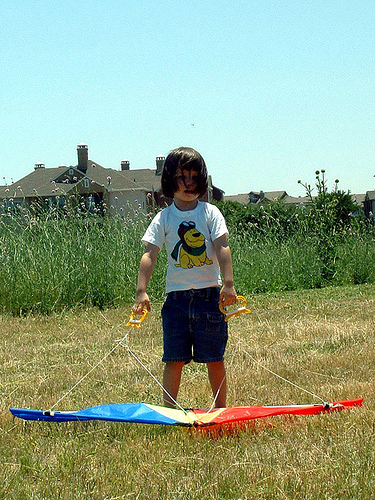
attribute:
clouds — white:
[223, 145, 282, 184]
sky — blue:
[1, 2, 363, 146]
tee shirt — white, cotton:
[140, 207, 232, 291]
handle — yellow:
[125, 306, 150, 332]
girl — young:
[137, 147, 239, 429]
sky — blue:
[2, 10, 331, 107]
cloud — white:
[229, 167, 285, 187]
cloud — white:
[251, 162, 296, 187]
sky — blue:
[204, 12, 339, 65]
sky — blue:
[2, 6, 98, 96]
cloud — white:
[95, 128, 129, 156]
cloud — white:
[256, 175, 294, 191]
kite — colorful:
[11, 396, 366, 425]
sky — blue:
[305, 6, 355, 67]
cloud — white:
[344, 167, 366, 191]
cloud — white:
[358, 177, 365, 185]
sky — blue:
[156, 10, 243, 93]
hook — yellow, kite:
[221, 293, 251, 318]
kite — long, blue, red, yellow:
[11, 394, 364, 428]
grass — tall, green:
[246, 229, 370, 286]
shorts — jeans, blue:
[163, 285, 228, 363]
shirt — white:
[139, 201, 230, 292]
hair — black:
[161, 145, 210, 201]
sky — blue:
[13, 10, 347, 53]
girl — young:
[122, 145, 244, 413]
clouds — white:
[1, 93, 371, 214]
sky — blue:
[1, 0, 369, 211]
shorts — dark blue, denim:
[161, 285, 233, 364]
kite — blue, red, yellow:
[11, 289, 365, 427]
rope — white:
[43, 325, 135, 417]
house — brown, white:
[0, 146, 224, 233]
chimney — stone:
[75, 142, 89, 171]